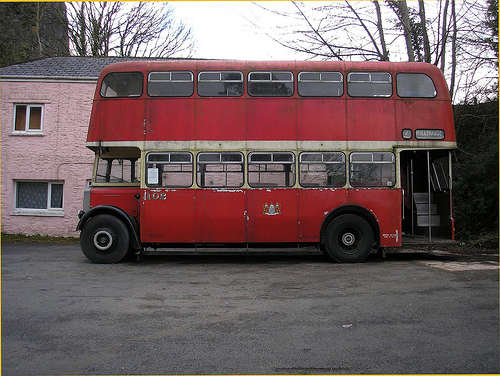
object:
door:
[399, 150, 449, 242]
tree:
[0, 2, 197, 60]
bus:
[71, 60, 458, 264]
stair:
[412, 215, 440, 227]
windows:
[195, 152, 247, 189]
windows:
[297, 150, 347, 189]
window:
[395, 71, 440, 100]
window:
[344, 72, 391, 99]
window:
[246, 71, 294, 96]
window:
[197, 68, 246, 98]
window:
[149, 68, 194, 98]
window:
[12, 104, 43, 134]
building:
[0, 54, 330, 241]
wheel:
[76, 213, 131, 265]